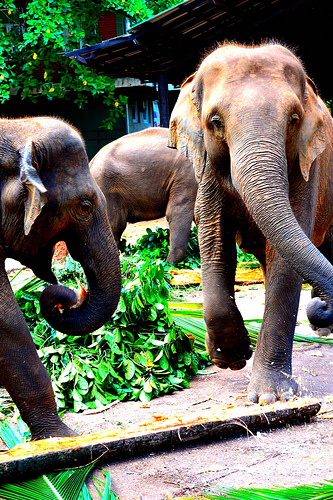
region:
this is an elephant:
[136, 23, 330, 441]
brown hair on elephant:
[163, 25, 324, 121]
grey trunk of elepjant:
[214, 102, 329, 345]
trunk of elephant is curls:
[13, 220, 130, 377]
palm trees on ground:
[0, 428, 107, 499]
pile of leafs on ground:
[11, 234, 197, 410]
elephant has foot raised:
[167, 243, 276, 373]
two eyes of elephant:
[194, 102, 307, 149]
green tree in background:
[0, 0, 127, 138]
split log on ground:
[13, 390, 326, 489]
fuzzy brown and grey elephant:
[163, 37, 332, 407]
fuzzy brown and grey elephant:
[0, 113, 123, 441]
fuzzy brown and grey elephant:
[85, 123, 203, 270]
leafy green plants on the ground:
[14, 245, 200, 413]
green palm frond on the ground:
[1, 450, 107, 498]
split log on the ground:
[1, 397, 327, 481]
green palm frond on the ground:
[191, 477, 332, 497]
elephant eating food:
[1, 113, 128, 447]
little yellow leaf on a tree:
[29, 50, 39, 61]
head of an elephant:
[183, 41, 321, 176]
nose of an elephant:
[25, 228, 181, 338]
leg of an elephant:
[8, 304, 70, 432]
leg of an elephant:
[177, 242, 267, 360]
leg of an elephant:
[240, 250, 321, 387]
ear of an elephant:
[7, 133, 66, 221]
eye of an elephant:
[54, 182, 97, 232]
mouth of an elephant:
[21, 248, 77, 290]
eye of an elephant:
[189, 72, 243, 150]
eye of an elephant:
[279, 100, 326, 131]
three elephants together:
[0, 58, 332, 413]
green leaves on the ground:
[21, 271, 167, 430]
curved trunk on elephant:
[34, 268, 152, 341]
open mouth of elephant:
[39, 234, 103, 302]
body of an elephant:
[88, 123, 198, 281]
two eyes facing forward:
[194, 89, 311, 153]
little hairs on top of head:
[204, 31, 304, 74]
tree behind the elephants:
[0, 0, 111, 131]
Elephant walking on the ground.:
[166, 40, 331, 412]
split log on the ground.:
[0, 396, 323, 479]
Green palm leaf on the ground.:
[0, 413, 92, 499]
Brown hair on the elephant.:
[194, 32, 303, 64]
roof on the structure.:
[59, 0, 328, 90]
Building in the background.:
[0, 1, 154, 165]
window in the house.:
[126, 94, 144, 126]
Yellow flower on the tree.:
[79, 78, 88, 87]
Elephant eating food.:
[0, 109, 122, 443]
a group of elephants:
[5, 7, 330, 439]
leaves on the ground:
[8, 407, 91, 497]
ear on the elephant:
[153, 78, 211, 175]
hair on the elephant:
[197, 29, 298, 67]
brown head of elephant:
[163, 23, 331, 160]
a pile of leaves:
[9, 239, 195, 408]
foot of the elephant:
[241, 350, 306, 410]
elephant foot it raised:
[186, 275, 258, 374]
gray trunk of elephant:
[232, 140, 331, 331]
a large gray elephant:
[162, 43, 332, 400]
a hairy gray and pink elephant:
[157, 38, 331, 402]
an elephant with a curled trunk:
[1, 121, 136, 450]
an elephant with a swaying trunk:
[163, 42, 332, 405]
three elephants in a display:
[0, 44, 332, 483]